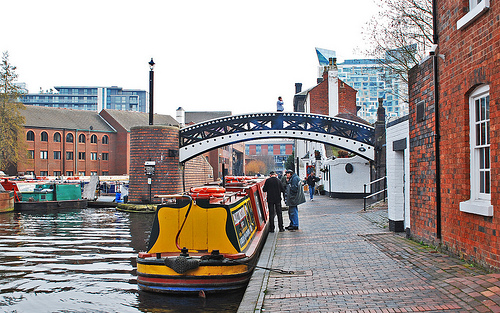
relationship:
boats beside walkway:
[137, 174, 269, 293] [238, 186, 500, 312]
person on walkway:
[264, 170, 286, 232] [238, 186, 500, 312]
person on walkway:
[284, 169, 307, 230] [238, 186, 500, 312]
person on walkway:
[307, 172, 322, 202] [238, 186, 500, 312]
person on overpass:
[277, 96, 284, 115] [179, 112, 374, 161]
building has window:
[410, 1, 500, 270] [459, 80, 494, 216]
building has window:
[17, 104, 133, 176] [40, 131, 50, 143]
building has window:
[17, 104, 133, 176] [53, 131, 62, 143]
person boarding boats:
[264, 170, 286, 232] [137, 174, 269, 293]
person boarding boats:
[284, 169, 307, 230] [137, 174, 269, 293]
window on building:
[40, 131, 50, 143] [17, 104, 133, 176]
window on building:
[53, 131, 62, 143] [17, 104, 133, 176]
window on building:
[67, 133, 75, 143] [17, 104, 133, 176]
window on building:
[78, 132, 87, 143] [17, 104, 133, 176]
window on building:
[89, 134, 99, 144] [17, 104, 133, 176]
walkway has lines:
[238, 186, 500, 312] [271, 238, 375, 249]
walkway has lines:
[238, 186, 500, 312] [265, 284, 442, 300]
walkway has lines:
[238, 186, 500, 312] [338, 302, 464, 311]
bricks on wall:
[419, 161, 428, 170] [409, 55, 441, 246]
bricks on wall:
[408, 138, 422, 147] [409, 55, 441, 246]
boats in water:
[137, 174, 269, 293] [0, 208, 247, 312]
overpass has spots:
[179, 112, 374, 161] [284, 130, 305, 135]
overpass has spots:
[179, 112, 374, 161] [185, 145, 197, 151]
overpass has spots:
[179, 112, 374, 161] [221, 133, 240, 141]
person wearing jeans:
[284, 169, 307, 230] [289, 205, 300, 228]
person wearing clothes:
[264, 170, 286, 232] [262, 177, 285, 229]